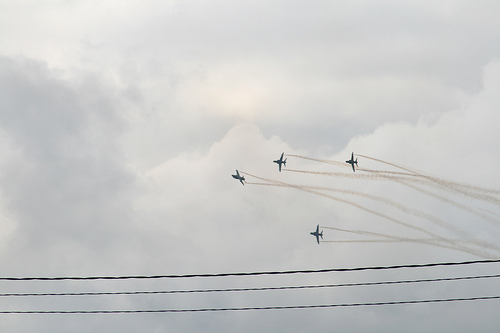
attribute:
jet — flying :
[344, 150, 358, 170]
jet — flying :
[271, 152, 287, 171]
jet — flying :
[309, 224, 324, 245]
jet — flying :
[231, 167, 245, 185]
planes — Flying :
[273, 149, 301, 171]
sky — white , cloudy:
[3, 6, 497, 330]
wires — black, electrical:
[6, 262, 499, 329]